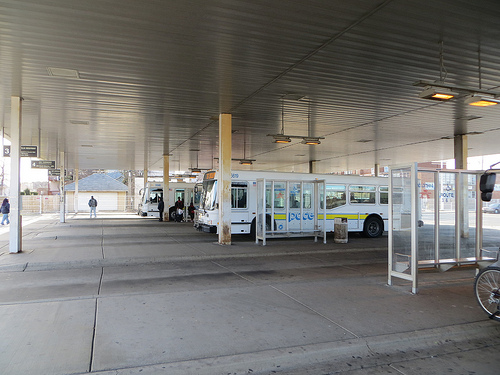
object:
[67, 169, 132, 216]
building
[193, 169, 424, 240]
bus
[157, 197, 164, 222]
people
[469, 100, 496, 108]
light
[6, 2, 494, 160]
ceiling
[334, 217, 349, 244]
trash can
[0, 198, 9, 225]
man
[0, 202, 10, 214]
jacket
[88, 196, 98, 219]
man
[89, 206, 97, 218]
pants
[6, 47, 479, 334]
station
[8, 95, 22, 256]
pole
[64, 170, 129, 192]
roof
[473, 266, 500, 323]
tire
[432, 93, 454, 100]
light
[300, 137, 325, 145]
light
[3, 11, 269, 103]
tile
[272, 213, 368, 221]
stripe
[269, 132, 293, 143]
light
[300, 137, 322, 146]
light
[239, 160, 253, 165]
light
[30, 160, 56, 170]
sign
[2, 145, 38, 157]
sign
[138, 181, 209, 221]
bus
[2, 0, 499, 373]
bus station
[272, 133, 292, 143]
light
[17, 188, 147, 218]
fence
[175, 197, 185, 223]
person